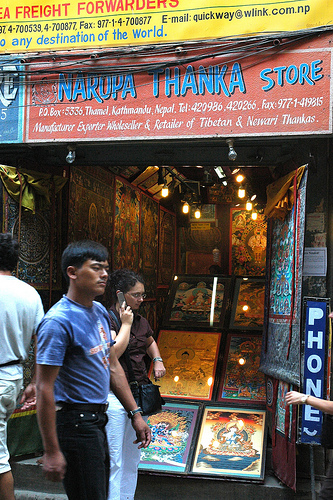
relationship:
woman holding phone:
[104, 268, 160, 500] [116, 290, 130, 314]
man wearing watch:
[33, 243, 148, 500] [127, 406, 144, 419]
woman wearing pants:
[104, 268, 160, 500] [107, 393, 143, 498]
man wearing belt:
[33, 243, 148, 500] [57, 399, 110, 413]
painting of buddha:
[153, 326, 212, 399] [175, 348, 198, 382]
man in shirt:
[2, 232, 43, 491] [2, 277, 44, 367]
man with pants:
[33, 243, 148, 500] [54, 401, 113, 496]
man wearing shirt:
[33, 243, 148, 500] [34, 297, 117, 404]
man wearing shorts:
[2, 232, 43, 491] [1, 364, 24, 474]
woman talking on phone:
[104, 268, 160, 500] [116, 290, 130, 314]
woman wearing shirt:
[104, 268, 160, 500] [109, 312, 153, 383]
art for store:
[139, 276, 272, 477] [26, 67, 331, 482]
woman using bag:
[104, 268, 160, 500] [126, 371, 162, 414]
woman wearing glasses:
[104, 268, 160, 500] [125, 290, 147, 298]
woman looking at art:
[104, 268, 160, 500] [139, 276, 272, 477]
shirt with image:
[34, 297, 117, 404] [93, 323, 110, 365]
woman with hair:
[104, 268, 160, 500] [107, 272, 141, 292]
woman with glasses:
[104, 268, 160, 500] [125, 290, 147, 298]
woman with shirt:
[104, 268, 160, 500] [109, 312, 153, 383]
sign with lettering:
[27, 47, 328, 138] [61, 61, 329, 95]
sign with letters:
[27, 47, 328, 138] [30, 95, 325, 131]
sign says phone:
[303, 299, 325, 443] [307, 310, 319, 422]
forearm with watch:
[288, 392, 330, 417] [300, 393, 310, 406]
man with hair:
[2, 232, 43, 491] [2, 236, 20, 270]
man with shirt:
[2, 232, 43, 491] [2, 277, 44, 367]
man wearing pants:
[33, 243, 148, 500] [54, 401, 113, 496]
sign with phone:
[303, 299, 325, 443] [307, 310, 319, 422]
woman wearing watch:
[104, 268, 160, 500] [149, 356, 165, 363]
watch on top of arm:
[300, 393, 310, 406] [288, 392, 330, 417]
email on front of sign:
[161, 5, 311, 21] [4, 0, 331, 45]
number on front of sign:
[178, 101, 257, 111] [27, 47, 328, 138]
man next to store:
[33, 243, 148, 500] [26, 67, 331, 482]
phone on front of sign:
[307, 310, 319, 422] [303, 299, 325, 443]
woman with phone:
[104, 268, 160, 500] [116, 290, 130, 314]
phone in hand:
[116, 290, 130, 314] [117, 302, 136, 323]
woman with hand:
[104, 268, 160, 500] [117, 302, 136, 323]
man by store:
[2, 232, 43, 491] [26, 67, 331, 482]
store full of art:
[26, 67, 331, 482] [139, 276, 272, 477]